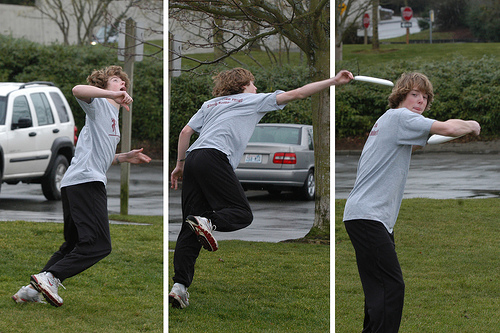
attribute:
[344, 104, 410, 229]
shirt — gray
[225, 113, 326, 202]
car — gray, parked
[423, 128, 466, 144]
frisbee — white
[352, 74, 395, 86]
frisbee — white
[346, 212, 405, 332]
pants — black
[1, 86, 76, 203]
suv — white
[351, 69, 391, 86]
frisbee — white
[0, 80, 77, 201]
jeep — white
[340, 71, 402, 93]
frisbee — white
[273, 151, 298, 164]
tail light — red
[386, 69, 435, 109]
hair — brown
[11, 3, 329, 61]
branches — bare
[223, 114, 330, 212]
car — gray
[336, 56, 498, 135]
green bush — large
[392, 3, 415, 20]
stop sign — red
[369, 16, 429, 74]
sign — white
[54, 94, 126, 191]
shirt — gray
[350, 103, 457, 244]
shirt — short sleeved, gray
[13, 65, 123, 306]
boy — running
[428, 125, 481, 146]
frisbee — white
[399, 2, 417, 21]
stop sign — red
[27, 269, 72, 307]
tennis shoes — white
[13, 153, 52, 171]
trim — black